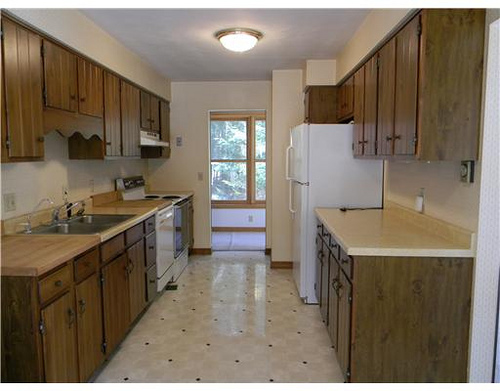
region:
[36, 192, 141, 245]
The sink is silver chrome.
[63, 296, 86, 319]
The kitchen cabinets have door knobs.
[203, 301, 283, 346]
The tile has black circles.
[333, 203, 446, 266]
The countertop is beige.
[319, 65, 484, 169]
The cabinets is brown.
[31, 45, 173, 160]
The cabinets are above the sink.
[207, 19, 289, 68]
The kitchen light is turned on.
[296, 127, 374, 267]
The refrigerator is white.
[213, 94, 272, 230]
The window is facing the kitchen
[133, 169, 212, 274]
The stove is in the corner.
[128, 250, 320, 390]
Black and white tile floor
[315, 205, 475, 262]
Yellowish kitchen counter on the right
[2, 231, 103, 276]
Butcherblock counter on the left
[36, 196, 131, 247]
Silver kitchen sink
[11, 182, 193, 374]
Row of wooden kitchen cabinets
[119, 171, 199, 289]
Black and white kitchen stove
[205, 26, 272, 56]
Round lit ceiling light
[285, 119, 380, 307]
White refrigerator and freezer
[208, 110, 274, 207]
Wooden frame windows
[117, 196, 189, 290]
White dishwasher near stove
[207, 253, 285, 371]
the floor is full of tiles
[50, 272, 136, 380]
the drawers is brown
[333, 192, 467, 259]
the top is made of ceramic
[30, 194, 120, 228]
the fosset is silver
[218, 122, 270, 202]
the trees are in the background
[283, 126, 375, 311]
the fridge is white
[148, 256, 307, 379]
the spots are black on the floor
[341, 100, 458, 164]
the cabinets are made of wood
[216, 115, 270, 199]
its daylight outside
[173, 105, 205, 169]
the walls are tan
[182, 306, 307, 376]
floor has tiles in it.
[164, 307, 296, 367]
brown color tiles in floor.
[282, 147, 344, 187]
fridge is white in color.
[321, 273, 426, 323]
cupboard are made of wood.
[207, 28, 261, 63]
light is seen in the ceiling.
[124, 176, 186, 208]
stove is white in color.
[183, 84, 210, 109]
walls are white color.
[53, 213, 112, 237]
sink is silver in color.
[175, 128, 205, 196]
switch are fixed to the walls.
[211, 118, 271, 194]
daytime picture.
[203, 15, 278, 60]
a light fixture on a ceiling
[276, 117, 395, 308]
a refrigerator next to a counter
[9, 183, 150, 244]
a silver sink in a kitchen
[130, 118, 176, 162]
a ventilation hood above a range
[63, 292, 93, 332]
door knobs on a cabinet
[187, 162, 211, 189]
a light switch on a wall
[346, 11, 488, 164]
brown cabinets against a wall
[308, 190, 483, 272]
a counter top in a kitchen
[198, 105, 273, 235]
windows in an adjoining room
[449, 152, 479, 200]
a thermostat on a wall